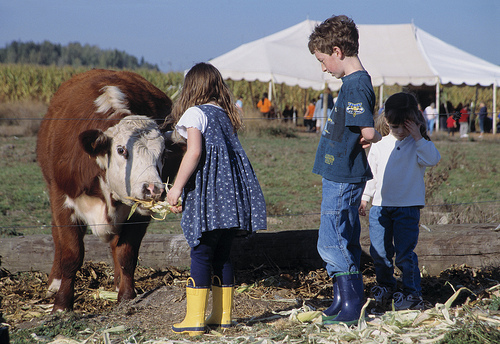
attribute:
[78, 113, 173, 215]
cow head — white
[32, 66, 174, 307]
cow — white, brown, large, red 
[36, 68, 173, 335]
cow — red 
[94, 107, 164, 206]
face — white 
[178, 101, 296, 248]
dress — floral 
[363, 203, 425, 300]
jeans — blue 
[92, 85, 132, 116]
spot — white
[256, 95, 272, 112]
shirt — orange 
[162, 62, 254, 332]
girl — little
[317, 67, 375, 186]
shirt — blue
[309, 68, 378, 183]
t-shirt — blue 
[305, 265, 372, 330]
boots — blue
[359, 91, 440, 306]
boy — Little 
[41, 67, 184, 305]
cow — brown, white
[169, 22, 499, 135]
canopy — white , large 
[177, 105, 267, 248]
dress — Blue , white 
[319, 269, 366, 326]
boots — Blue , green 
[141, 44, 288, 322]
girl — girl's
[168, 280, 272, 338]
boots — yellow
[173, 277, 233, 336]
boots — yellow 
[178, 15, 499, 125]
tent — white 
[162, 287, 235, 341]
boots — Yellow, blue 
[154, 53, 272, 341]
girl — little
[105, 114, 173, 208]
face — white 